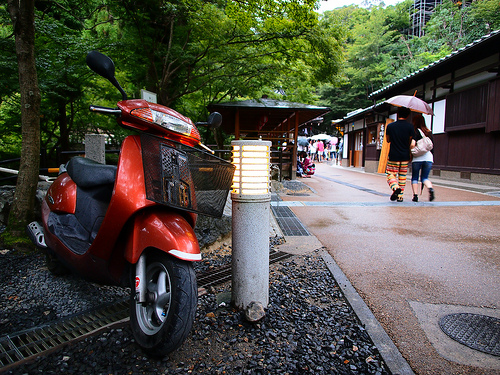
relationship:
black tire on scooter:
[121, 244, 206, 366] [31, 52, 218, 357]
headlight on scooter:
[126, 95, 204, 154] [28, 75, 230, 367]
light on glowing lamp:
[222, 132, 278, 201] [225, 137, 274, 311]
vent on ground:
[4, 283, 154, 373] [4, 173, 497, 373]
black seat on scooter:
[66, 153, 128, 197] [31, 52, 218, 357]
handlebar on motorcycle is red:
[82, 99, 134, 126] [28, 45, 203, 370]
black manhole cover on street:
[439, 305, 500, 359] [289, 159, 498, 371]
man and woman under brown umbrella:
[380, 90, 454, 211] [382, 90, 437, 117]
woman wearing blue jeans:
[407, 122, 446, 212] [409, 161, 432, 189]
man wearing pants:
[378, 111, 424, 211] [383, 155, 412, 199]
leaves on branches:
[259, 7, 345, 98] [216, 25, 303, 80]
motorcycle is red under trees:
[28, 45, 203, 370] [2, 1, 349, 233]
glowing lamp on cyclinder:
[225, 128, 282, 327] [229, 194, 274, 319]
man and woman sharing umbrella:
[380, 103, 435, 203] [388, 90, 431, 115]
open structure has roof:
[211, 100, 331, 191] [213, 95, 325, 124]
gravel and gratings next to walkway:
[268, 255, 403, 374] [293, 155, 498, 365]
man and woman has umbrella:
[380, 103, 435, 203] [386, 90, 427, 113]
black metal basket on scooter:
[136, 123, 259, 228] [31, 52, 218, 357]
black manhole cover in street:
[431, 305, 499, 369] [289, 159, 498, 371]